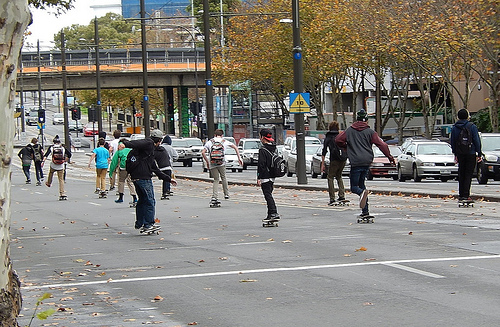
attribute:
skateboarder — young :
[251, 119, 294, 230]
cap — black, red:
[256, 127, 275, 143]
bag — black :
[268, 147, 291, 177]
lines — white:
[24, 246, 497, 325]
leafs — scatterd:
[34, 216, 237, 309]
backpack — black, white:
[456, 121, 471, 154]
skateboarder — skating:
[338, 110, 399, 230]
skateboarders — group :
[96, 134, 388, 203]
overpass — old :
[10, 33, 267, 99]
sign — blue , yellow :
[280, 83, 336, 126]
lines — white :
[4, 249, 498, 322]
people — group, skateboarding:
[17, 106, 499, 234]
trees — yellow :
[222, 15, 499, 121]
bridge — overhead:
[34, 60, 194, 73]